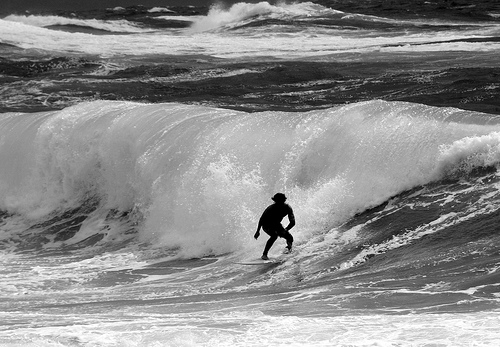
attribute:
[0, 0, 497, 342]
water — steered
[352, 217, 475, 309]
water — choppy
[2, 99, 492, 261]
waters — choppy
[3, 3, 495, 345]
ocean water — wavy, choppy